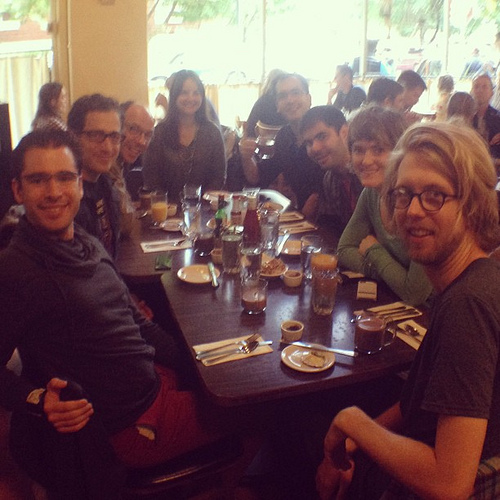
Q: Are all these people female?
A: No, they are both male and female.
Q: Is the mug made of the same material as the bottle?
A: Yes, both the mug and the bottle are made of glass.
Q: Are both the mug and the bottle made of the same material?
A: Yes, both the mug and the bottle are made of glass.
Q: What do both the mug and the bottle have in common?
A: The material, both the mug and the bottle are glass.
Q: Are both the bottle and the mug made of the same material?
A: Yes, both the bottle and the mug are made of glass.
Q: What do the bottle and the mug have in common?
A: The material, both the bottle and the mug are glass.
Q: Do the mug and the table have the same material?
A: No, the mug is made of glass and the table is made of wood.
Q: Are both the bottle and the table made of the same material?
A: No, the bottle is made of glass and the table is made of wood.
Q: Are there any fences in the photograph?
A: No, there are no fences.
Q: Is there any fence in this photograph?
A: No, there are no fences.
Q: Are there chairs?
A: Yes, there is a chair.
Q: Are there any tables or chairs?
A: Yes, there is a chair.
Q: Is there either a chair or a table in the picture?
A: Yes, there is a chair.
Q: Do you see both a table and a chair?
A: Yes, there are both a chair and a table.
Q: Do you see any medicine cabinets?
A: No, there are no medicine cabinets.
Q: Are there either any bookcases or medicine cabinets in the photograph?
A: No, there are no medicine cabinets or bookcases.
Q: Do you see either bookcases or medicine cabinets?
A: No, there are no medicine cabinets or bookcases.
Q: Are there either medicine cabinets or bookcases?
A: No, there are no medicine cabinets or bookcases.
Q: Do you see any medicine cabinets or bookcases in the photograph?
A: No, there are no medicine cabinets or bookcases.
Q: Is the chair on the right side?
A: Yes, the chair is on the right of the image.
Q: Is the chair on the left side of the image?
A: No, the chair is on the right of the image.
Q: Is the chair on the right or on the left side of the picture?
A: The chair is on the right of the image.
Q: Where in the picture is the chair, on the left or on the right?
A: The chair is on the right of the image.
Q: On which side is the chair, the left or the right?
A: The chair is on the right of the image.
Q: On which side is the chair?
A: The chair is on the right of the image.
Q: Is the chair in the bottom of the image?
A: Yes, the chair is in the bottom of the image.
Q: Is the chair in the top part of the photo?
A: No, the chair is in the bottom of the image.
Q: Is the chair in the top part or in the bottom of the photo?
A: The chair is in the bottom of the image.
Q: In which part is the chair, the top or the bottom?
A: The chair is in the bottom of the image.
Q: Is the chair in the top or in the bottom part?
A: The chair is in the bottom of the image.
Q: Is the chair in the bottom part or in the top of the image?
A: The chair is in the bottom of the image.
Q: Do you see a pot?
A: No, there are no pots.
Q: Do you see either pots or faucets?
A: No, there are no pots or faucets.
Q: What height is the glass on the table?
A: The glass is tall.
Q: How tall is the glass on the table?
A: The glass is tall.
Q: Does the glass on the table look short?
A: No, the glass is tall.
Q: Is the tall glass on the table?
A: Yes, the glass is on the table.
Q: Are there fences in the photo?
A: No, there are no fences.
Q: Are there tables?
A: Yes, there is a table.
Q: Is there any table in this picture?
A: Yes, there is a table.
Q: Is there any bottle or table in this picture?
A: Yes, there is a table.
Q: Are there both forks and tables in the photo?
A: Yes, there are both a table and a fork.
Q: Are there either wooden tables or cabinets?
A: Yes, there is a wood table.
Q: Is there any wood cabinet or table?
A: Yes, there is a wood table.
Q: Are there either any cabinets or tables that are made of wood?
A: Yes, the table is made of wood.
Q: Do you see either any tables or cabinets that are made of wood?
A: Yes, the table is made of wood.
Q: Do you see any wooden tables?
A: Yes, there is a wood table.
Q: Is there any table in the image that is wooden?
A: Yes, there is a table that is wooden.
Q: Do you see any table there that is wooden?
A: Yes, there is a table that is wooden.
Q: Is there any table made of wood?
A: Yes, there is a table that is made of wood.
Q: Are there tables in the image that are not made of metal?
A: Yes, there is a table that is made of wood.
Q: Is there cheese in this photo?
A: No, there is no cheese.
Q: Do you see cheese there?
A: No, there is no cheese.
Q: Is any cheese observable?
A: No, there is no cheese.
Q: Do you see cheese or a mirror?
A: No, there are no cheese or mirrors.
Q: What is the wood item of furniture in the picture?
A: The piece of furniture is a table.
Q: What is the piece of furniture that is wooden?
A: The piece of furniture is a table.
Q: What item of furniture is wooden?
A: The piece of furniture is a table.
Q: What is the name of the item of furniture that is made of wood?
A: The piece of furniture is a table.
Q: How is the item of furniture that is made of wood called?
A: The piece of furniture is a table.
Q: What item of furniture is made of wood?
A: The piece of furniture is a table.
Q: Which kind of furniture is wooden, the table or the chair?
A: The table is wooden.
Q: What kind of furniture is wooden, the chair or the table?
A: The table is wooden.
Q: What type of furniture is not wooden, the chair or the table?
A: The chair is not wooden.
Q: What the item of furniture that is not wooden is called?
A: The piece of furniture is a chair.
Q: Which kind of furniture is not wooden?
A: The furniture is a chair.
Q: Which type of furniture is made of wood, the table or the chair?
A: The table is made of wood.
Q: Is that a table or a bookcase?
A: That is a table.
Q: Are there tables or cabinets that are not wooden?
A: No, there is a table but it is wooden.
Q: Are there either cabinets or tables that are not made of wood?
A: No, there is a table but it is made of wood.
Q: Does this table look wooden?
A: Yes, the table is wooden.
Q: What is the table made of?
A: The table is made of wood.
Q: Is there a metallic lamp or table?
A: No, there is a table but it is wooden.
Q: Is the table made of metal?
A: No, the table is made of wood.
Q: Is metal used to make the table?
A: No, the table is made of wood.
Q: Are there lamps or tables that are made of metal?
A: No, there is a table but it is made of wood.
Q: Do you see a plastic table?
A: No, there is a table but it is made of wood.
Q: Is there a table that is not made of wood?
A: No, there is a table but it is made of wood.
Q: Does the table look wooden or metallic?
A: The table is wooden.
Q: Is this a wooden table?
A: Yes, this is a wooden table.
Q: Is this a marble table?
A: No, this is a wooden table.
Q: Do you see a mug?
A: Yes, there is a mug.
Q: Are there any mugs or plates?
A: Yes, there is a mug.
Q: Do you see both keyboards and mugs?
A: No, there is a mug but no keyboards.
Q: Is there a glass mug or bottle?
A: Yes, there is a glass mug.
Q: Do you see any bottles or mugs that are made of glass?
A: Yes, the mug is made of glass.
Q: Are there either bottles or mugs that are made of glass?
A: Yes, the mug is made of glass.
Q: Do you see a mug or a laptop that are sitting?
A: Yes, the mug is sitting.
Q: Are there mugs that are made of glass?
A: Yes, there is a mug that is made of glass.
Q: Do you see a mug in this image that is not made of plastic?
A: Yes, there is a mug that is made of glass.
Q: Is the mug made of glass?
A: Yes, the mug is made of glass.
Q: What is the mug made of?
A: The mug is made of glass.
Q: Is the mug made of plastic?
A: No, the mug is made of glass.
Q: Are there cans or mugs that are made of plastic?
A: No, there is a mug but it is made of glass.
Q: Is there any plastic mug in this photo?
A: No, there is a mug but it is made of glass.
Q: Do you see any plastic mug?
A: No, there is a mug but it is made of glass.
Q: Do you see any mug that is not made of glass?
A: No, there is a mug but it is made of glass.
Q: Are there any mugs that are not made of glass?
A: No, there is a mug but it is made of glass.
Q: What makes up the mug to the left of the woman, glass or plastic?
A: The mug is made of glass.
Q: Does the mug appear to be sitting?
A: Yes, the mug is sitting.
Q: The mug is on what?
A: The mug is on the table.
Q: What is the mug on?
A: The mug is on the table.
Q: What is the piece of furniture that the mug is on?
A: The piece of furniture is a table.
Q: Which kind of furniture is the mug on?
A: The mug is on the table.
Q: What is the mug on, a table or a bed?
A: The mug is on a table.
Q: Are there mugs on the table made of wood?
A: Yes, there is a mug on the table.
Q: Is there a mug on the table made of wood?
A: Yes, there is a mug on the table.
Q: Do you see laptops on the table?
A: No, there is a mug on the table.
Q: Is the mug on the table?
A: Yes, the mug is on the table.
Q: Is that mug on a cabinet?
A: No, the mug is on the table.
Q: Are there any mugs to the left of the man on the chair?
A: Yes, there is a mug to the left of the man.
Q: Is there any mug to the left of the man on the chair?
A: Yes, there is a mug to the left of the man.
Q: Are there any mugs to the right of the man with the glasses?
A: No, the mug is to the left of the man.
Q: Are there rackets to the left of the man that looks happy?
A: No, there is a mug to the left of the man.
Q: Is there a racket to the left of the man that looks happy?
A: No, there is a mug to the left of the man.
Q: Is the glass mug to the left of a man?
A: Yes, the mug is to the left of a man.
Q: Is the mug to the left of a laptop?
A: No, the mug is to the left of a man.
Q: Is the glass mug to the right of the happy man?
A: No, the mug is to the left of the man.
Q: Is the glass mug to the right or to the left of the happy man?
A: The mug is to the left of the man.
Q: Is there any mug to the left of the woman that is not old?
A: Yes, there is a mug to the left of the woman.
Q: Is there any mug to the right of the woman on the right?
A: No, the mug is to the left of the woman.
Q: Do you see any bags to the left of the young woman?
A: No, there is a mug to the left of the woman.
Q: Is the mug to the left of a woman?
A: Yes, the mug is to the left of a woman.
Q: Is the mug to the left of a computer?
A: No, the mug is to the left of a woman.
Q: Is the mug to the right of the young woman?
A: No, the mug is to the left of the woman.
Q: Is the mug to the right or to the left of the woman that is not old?
A: The mug is to the left of the woman.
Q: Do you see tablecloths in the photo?
A: No, there are no tablecloths.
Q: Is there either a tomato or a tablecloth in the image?
A: No, there are no tablecloths or tomatoes.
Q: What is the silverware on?
A: The silverware is on the napkin.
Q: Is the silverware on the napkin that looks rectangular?
A: Yes, the silverware is on the napkin.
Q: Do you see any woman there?
A: Yes, there is a woman.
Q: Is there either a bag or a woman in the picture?
A: Yes, there is a woman.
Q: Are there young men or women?
A: Yes, there is a young woman.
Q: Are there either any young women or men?
A: Yes, there is a young woman.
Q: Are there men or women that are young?
A: Yes, the woman is young.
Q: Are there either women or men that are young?
A: Yes, the woman is young.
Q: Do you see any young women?
A: Yes, there is a young woman.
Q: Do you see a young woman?
A: Yes, there is a young woman.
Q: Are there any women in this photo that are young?
A: Yes, there is a woman that is young.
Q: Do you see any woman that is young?
A: Yes, there is a woman that is young.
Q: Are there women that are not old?
A: Yes, there is an young woman.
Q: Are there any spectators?
A: No, there are no spectators.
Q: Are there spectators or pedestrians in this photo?
A: No, there are no spectators or pedestrians.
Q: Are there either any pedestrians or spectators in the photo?
A: No, there are no spectators or pedestrians.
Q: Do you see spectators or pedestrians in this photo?
A: No, there are no spectators or pedestrians.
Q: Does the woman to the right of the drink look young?
A: Yes, the woman is young.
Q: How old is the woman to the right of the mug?
A: The woman is young.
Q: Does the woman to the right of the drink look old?
A: No, the woman is young.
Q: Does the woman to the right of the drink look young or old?
A: The woman is young.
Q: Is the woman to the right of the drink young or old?
A: The woman is young.